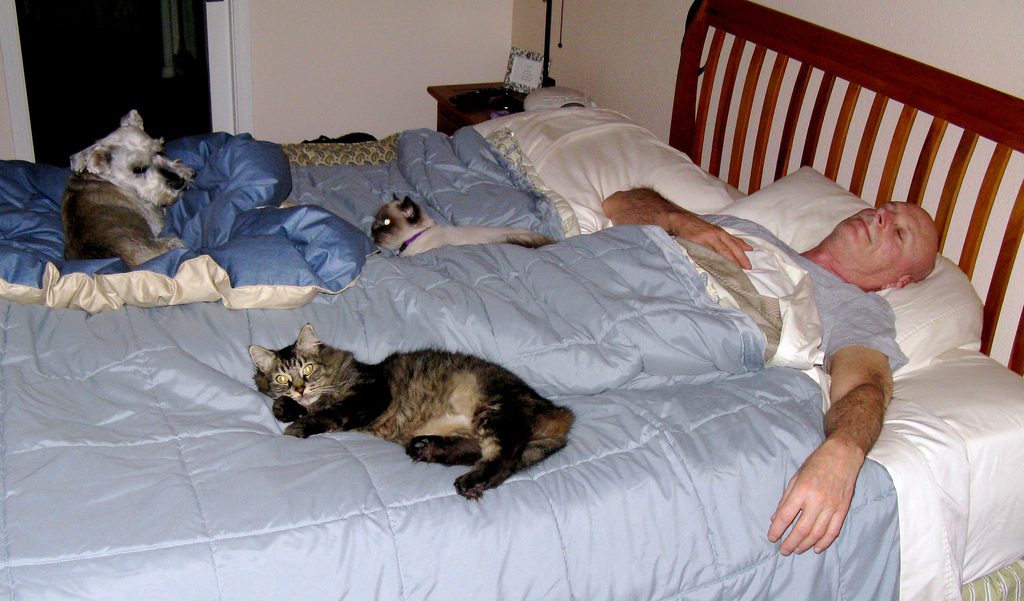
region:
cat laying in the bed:
[231, 316, 585, 514]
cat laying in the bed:
[367, 181, 555, 258]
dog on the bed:
[46, 113, 202, 290]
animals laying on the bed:
[25, 104, 852, 586]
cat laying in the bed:
[63, 101, 196, 264]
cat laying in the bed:
[239, 306, 578, 519]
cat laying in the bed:
[340, 173, 566, 253]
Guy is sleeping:
[0, 181, 943, 584]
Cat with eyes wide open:
[245, 315, 578, 505]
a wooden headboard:
[661, 2, 1020, 376]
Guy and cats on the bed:
[0, 1, 1023, 597]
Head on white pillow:
[691, 160, 989, 388]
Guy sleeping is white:
[0, 181, 945, 564]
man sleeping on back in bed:
[582, 168, 952, 568]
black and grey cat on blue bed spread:
[241, 314, 581, 504]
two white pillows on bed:
[469, 94, 988, 386]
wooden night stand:
[421, 72, 530, 133]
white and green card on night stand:
[497, 39, 548, 98]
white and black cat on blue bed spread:
[361, 180, 561, 266]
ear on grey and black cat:
[238, 336, 278, 372]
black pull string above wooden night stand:
[551, 3, 572, 54]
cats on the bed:
[68, 54, 830, 583]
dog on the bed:
[27, 35, 244, 375]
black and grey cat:
[194, 282, 793, 595]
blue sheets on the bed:
[27, 86, 795, 551]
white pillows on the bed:
[451, 63, 1017, 481]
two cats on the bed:
[245, 100, 539, 592]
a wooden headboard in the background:
[637, 6, 1012, 444]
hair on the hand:
[755, 275, 929, 595]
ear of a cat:
[247, 343, 276, 369]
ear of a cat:
[296, 327, 320, 356]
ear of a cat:
[400, 194, 423, 223]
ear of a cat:
[389, 194, 402, 202]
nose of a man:
[874, 205, 885, 224]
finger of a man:
[766, 492, 802, 541]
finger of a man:
[778, 505, 807, 556]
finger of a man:
[794, 502, 824, 548]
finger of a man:
[817, 507, 838, 547]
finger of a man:
[725, 232, 755, 267]